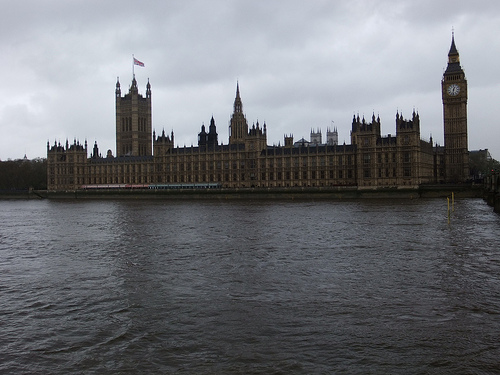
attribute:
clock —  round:
[443, 80, 462, 97]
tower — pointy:
[215, 71, 272, 151]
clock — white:
[446, 82, 459, 96]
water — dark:
[210, 222, 429, 323]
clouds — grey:
[1, 0, 498, 160]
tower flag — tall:
[113, 51, 155, 193]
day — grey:
[0, 10, 497, 242]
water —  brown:
[52, 214, 406, 333]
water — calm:
[0, 194, 497, 372]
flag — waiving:
[120, 48, 199, 87]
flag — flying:
[105, 57, 160, 99]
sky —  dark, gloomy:
[1, 2, 499, 159]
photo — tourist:
[104, 110, 475, 183]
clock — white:
[443, 79, 463, 99]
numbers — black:
[447, 84, 458, 100]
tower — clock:
[439, 29, 469, 174]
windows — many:
[261, 149, 353, 185]